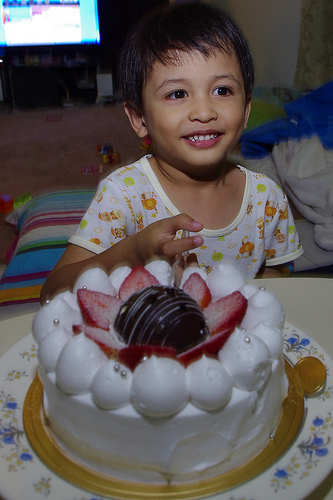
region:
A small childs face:
[118, 6, 264, 165]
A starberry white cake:
[31, 256, 289, 485]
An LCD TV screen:
[0, 1, 107, 47]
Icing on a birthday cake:
[56, 342, 274, 481]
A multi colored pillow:
[7, 186, 103, 295]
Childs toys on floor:
[68, 138, 122, 181]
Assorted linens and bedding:
[247, 72, 332, 261]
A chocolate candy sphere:
[118, 282, 206, 349]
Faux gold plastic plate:
[278, 350, 324, 445]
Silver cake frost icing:
[242, 333, 251, 349]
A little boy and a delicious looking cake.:
[33, 4, 303, 484]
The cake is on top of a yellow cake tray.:
[21, 260, 325, 499]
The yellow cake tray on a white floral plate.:
[0, 317, 331, 499]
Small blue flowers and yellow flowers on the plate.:
[0, 319, 331, 497]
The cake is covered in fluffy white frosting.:
[30, 259, 287, 484]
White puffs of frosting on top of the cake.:
[33, 260, 283, 418]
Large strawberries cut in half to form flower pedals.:
[71, 264, 247, 372]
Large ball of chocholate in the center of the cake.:
[111, 283, 205, 353]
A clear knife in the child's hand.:
[134, 211, 203, 292]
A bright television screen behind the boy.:
[0, 0, 100, 47]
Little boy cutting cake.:
[2, 0, 331, 497]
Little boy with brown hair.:
[36, 0, 304, 325]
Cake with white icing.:
[20, 246, 324, 496]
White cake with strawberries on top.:
[18, 254, 300, 493]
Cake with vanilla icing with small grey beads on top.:
[27, 256, 292, 486]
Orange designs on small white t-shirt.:
[66, 156, 304, 287]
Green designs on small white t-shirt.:
[65, 147, 306, 282]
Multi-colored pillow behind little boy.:
[0, 186, 303, 307]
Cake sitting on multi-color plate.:
[0, 302, 332, 499]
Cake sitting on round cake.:
[0, 318, 330, 497]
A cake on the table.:
[48, 273, 295, 455]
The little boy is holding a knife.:
[151, 207, 207, 248]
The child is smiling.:
[173, 120, 227, 155]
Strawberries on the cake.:
[203, 285, 238, 335]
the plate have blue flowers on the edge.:
[293, 421, 328, 467]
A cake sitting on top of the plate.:
[18, 326, 300, 488]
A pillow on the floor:
[10, 185, 83, 274]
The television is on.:
[6, 11, 94, 55]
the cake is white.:
[60, 375, 247, 465]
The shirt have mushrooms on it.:
[241, 236, 285, 262]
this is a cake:
[24, 234, 307, 488]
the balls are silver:
[238, 330, 254, 345]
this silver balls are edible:
[106, 357, 131, 381]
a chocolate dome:
[113, 278, 214, 341]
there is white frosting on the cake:
[15, 248, 320, 482]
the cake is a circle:
[23, 245, 315, 479]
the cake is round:
[26, 242, 318, 498]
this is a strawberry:
[78, 283, 122, 328]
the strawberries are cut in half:
[77, 269, 255, 389]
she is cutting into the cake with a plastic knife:
[80, 13, 326, 348]